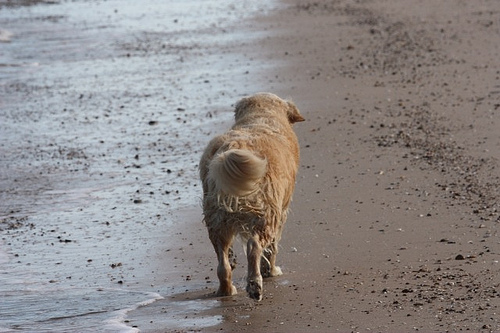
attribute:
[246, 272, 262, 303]
paw — of the dog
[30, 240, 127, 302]
sand — wet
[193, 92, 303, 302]
dog — shaggy, tan, wet, medium sized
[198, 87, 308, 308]
dog — tan, on the sand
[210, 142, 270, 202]
tail — tan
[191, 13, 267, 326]
line — water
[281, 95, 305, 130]
ear — tan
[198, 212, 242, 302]
leg — tan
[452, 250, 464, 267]
rock — little, black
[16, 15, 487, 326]
beach — wet, sandy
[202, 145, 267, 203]
tail — white